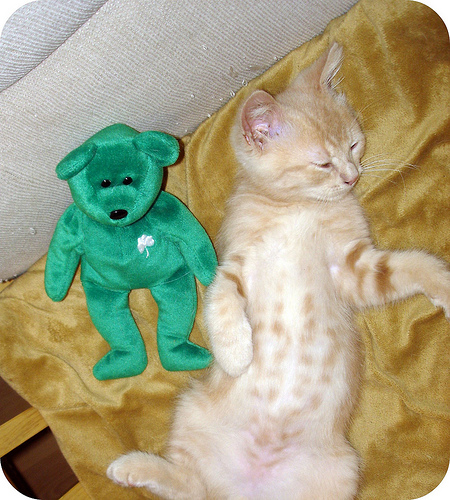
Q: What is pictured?
A: A kitten.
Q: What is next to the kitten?
A: A green beanie baby bear.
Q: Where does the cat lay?
A: On a gold cushion.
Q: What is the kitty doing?
A: Sleeping.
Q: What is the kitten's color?
A: Orange and white.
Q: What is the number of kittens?
A: One.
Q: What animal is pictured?
A: Cat.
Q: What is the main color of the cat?
A: Orange and white.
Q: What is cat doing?
A: Laying on his back.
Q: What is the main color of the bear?
A: Green.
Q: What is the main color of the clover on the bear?
A: White.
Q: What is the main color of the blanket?
A: Orange.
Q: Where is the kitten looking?
A: Away from the bear.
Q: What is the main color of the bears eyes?
A: Black.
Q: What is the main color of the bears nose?
A: Black.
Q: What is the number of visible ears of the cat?
A: 2.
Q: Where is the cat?
A: On a pillow.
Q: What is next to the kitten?
A: Beanie Baby.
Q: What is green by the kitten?
A: Teddy bear.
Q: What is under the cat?
A: Cushion.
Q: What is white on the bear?
A: Shamrock.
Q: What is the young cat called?
A: A kitten.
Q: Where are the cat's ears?
A: On the cat's head.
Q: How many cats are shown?
A: 1.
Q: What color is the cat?
A: Orange.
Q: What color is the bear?
A: Green.